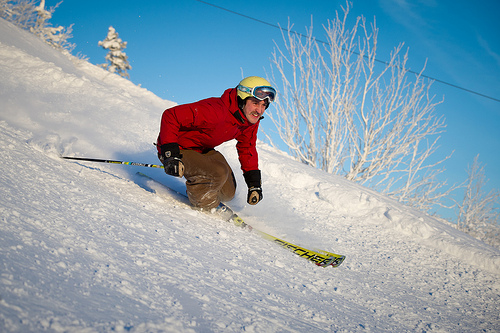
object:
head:
[237, 74, 279, 124]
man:
[156, 76, 278, 214]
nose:
[255, 105, 263, 114]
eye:
[252, 102, 258, 106]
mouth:
[253, 111, 259, 117]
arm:
[155, 96, 220, 162]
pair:
[249, 84, 278, 101]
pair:
[135, 170, 348, 269]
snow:
[1, 17, 499, 329]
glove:
[241, 169, 264, 206]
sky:
[1, 1, 498, 232]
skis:
[134, 169, 347, 268]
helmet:
[236, 75, 276, 107]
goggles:
[252, 85, 277, 103]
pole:
[59, 155, 165, 170]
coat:
[156, 86, 265, 170]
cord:
[196, 1, 499, 104]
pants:
[156, 142, 237, 212]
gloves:
[157, 142, 186, 179]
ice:
[97, 24, 133, 81]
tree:
[96, 24, 133, 83]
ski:
[94, 165, 336, 268]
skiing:
[1, 3, 498, 331]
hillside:
[1, 15, 500, 332]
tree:
[239, 12, 447, 187]